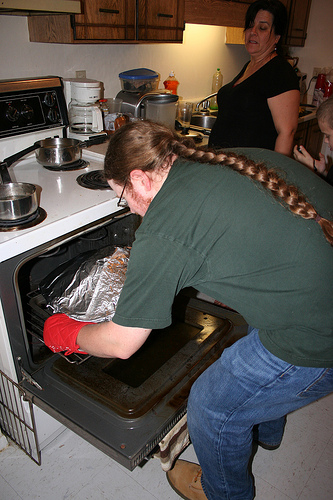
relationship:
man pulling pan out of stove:
[76, 118, 331, 498] [0, 76, 250, 475]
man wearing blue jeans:
[76, 118, 331, 498] [186, 330, 332, 499]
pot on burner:
[39, 135, 83, 163] [43, 155, 88, 171]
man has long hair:
[76, 118, 331, 498] [114, 125, 332, 239]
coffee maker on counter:
[61, 76, 104, 138] [97, 121, 222, 171]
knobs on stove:
[47, 89, 59, 124] [0, 76, 250, 475]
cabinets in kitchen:
[38, 6, 247, 41] [2, 1, 332, 499]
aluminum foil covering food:
[42, 241, 134, 323] [47, 240, 147, 331]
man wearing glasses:
[76, 118, 331, 498] [112, 180, 130, 207]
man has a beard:
[76, 118, 331, 498] [128, 189, 161, 213]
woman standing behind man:
[215, 1, 301, 154] [76, 118, 331, 498]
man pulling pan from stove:
[76, 118, 331, 498] [0, 76, 250, 475]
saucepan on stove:
[0, 182, 42, 220] [2, 145, 136, 247]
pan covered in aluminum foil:
[47, 240, 147, 331] [42, 241, 134, 323]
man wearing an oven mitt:
[76, 118, 331, 498] [40, 312, 105, 356]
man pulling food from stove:
[76, 118, 331, 498] [0, 76, 250, 475]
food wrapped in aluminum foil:
[47, 240, 147, 331] [42, 241, 134, 323]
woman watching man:
[215, 1, 301, 154] [76, 118, 331, 498]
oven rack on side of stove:
[2, 377, 42, 463] [0, 76, 250, 475]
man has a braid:
[76, 118, 331, 498] [114, 125, 332, 239]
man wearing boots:
[76, 118, 331, 498] [167, 457, 212, 499]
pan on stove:
[39, 135, 83, 163] [2, 145, 136, 247]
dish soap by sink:
[167, 73, 179, 97] [187, 108, 234, 129]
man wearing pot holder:
[76, 118, 331, 498] [40, 312, 105, 356]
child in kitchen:
[310, 99, 332, 177] [2, 1, 332, 499]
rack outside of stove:
[2, 377, 42, 463] [0, 76, 250, 475]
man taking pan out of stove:
[76, 118, 331, 498] [0, 76, 250, 475]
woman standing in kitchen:
[215, 1, 301, 154] [2, 1, 332, 499]